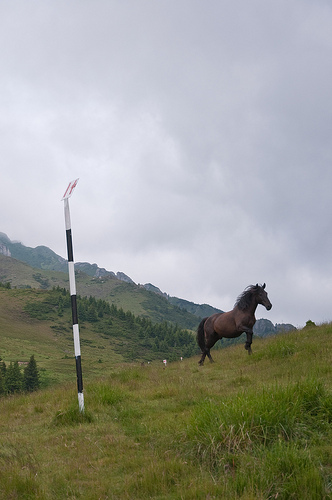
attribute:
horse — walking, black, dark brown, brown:
[196, 280, 275, 366]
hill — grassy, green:
[2, 322, 331, 499]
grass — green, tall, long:
[228, 440, 330, 499]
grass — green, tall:
[185, 375, 323, 431]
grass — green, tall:
[255, 332, 302, 359]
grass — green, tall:
[50, 406, 97, 429]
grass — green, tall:
[3, 468, 39, 500]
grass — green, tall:
[85, 378, 123, 405]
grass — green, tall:
[107, 367, 140, 383]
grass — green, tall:
[116, 406, 150, 439]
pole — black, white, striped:
[61, 197, 87, 416]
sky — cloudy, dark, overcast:
[0, 1, 330, 325]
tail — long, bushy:
[196, 317, 209, 353]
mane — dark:
[236, 284, 257, 311]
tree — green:
[23, 354, 41, 396]